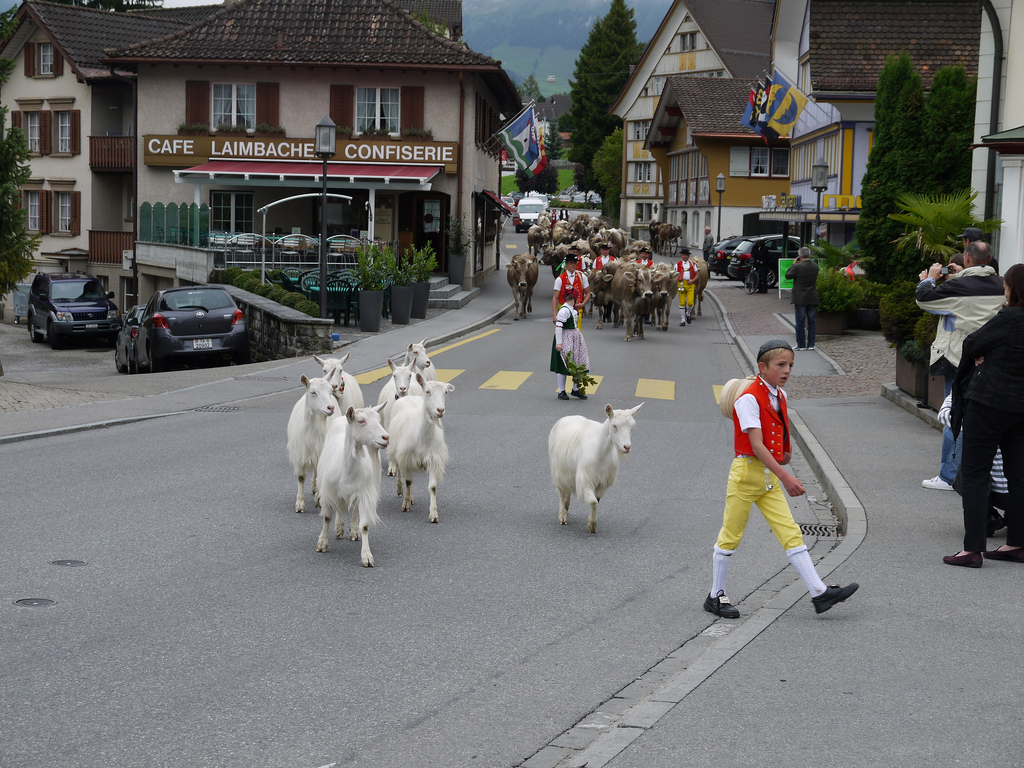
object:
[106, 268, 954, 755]
street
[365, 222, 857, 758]
street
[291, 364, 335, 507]
animals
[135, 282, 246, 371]
car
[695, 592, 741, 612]
shoe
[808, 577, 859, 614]
shoe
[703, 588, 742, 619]
foot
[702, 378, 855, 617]
outfit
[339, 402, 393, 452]
head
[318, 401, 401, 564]
animal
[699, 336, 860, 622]
boy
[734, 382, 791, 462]
vest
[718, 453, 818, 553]
pants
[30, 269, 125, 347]
suv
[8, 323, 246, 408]
road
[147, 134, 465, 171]
sign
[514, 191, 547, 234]
van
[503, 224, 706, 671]
road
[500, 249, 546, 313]
cattle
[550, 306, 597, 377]
dress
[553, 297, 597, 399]
girl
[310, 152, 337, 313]
light pole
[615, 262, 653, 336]
cattle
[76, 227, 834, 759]
road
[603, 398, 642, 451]
head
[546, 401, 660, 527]
animal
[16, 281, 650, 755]
street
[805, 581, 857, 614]
foot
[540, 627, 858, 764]
curb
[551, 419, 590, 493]
fur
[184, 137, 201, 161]
words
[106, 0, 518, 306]
building